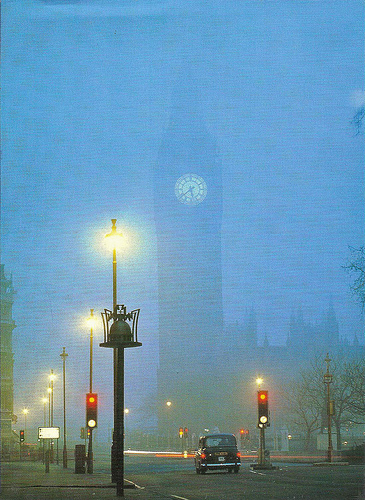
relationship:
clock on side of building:
[173, 170, 215, 212] [154, 53, 224, 441]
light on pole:
[99, 233, 132, 250] [101, 218, 129, 297]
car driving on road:
[190, 436, 242, 473] [220, 480, 269, 492]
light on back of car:
[200, 449, 207, 459] [190, 436, 242, 473]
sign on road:
[35, 426, 67, 447] [0, 453, 365, 500]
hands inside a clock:
[186, 187, 196, 198] [173, 170, 215, 212]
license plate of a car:
[218, 456, 226, 465] [190, 436, 242, 473]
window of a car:
[207, 439, 234, 447] [190, 436, 242, 473]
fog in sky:
[41, 33, 136, 108] [36, 41, 86, 76]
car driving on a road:
[190, 436, 242, 473] [220, 480, 269, 492]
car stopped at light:
[190, 436, 242, 473] [257, 391, 268, 403]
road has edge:
[220, 480, 269, 492] [129, 476, 140, 485]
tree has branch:
[331, 370, 360, 417] [331, 367, 342, 389]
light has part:
[99, 233, 132, 250] [114, 235, 123, 245]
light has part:
[99, 233, 132, 250] [116, 237, 125, 246]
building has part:
[145, 44, 231, 430] [203, 255, 213, 276]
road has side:
[220, 480, 269, 492] [148, 472, 154, 483]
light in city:
[99, 233, 132, 250] [2, 75, 364, 495]